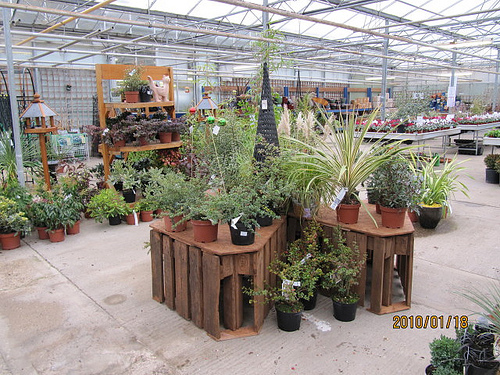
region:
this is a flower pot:
[255, 280, 318, 335]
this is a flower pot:
[326, 276, 358, 321]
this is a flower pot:
[221, 200, 262, 245]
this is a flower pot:
[185, 203, 222, 238]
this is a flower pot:
[140, 173, 191, 225]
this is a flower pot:
[295, 130, 391, 220]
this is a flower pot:
[368, 160, 410, 226]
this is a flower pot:
[403, 150, 468, 240]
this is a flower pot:
[418, 336, 458, 371]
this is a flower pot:
[94, 187, 131, 225]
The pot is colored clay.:
[184, 195, 234, 249]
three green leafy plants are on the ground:
[266, 214, 374, 336]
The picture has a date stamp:
[390, 307, 475, 347]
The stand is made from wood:
[156, 212, 246, 336]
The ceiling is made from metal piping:
[167, 30, 212, 74]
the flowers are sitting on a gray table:
[357, 110, 457, 153]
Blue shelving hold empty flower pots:
[337, 77, 379, 119]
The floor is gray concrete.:
[40, 260, 126, 341]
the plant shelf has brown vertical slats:
[141, 213, 224, 344]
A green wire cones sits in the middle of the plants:
[250, 56, 290, 158]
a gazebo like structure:
[13, 90, 65, 142]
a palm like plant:
[299, 100, 400, 237]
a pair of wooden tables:
[150, 185, 443, 337]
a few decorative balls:
[167, 99, 234, 135]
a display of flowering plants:
[352, 105, 469, 138]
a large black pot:
[416, 200, 451, 232]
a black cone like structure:
[246, 62, 298, 199]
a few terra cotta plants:
[21, 216, 85, 241]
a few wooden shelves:
[83, 55, 190, 209]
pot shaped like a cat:
[143, 70, 180, 112]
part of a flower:
[291, 275, 303, 294]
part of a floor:
[50, 229, 80, 330]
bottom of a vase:
[288, 324, 294, 329]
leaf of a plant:
[231, 172, 243, 179]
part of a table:
[439, 145, 466, 177]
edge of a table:
[424, 121, 444, 136]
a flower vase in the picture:
[267, 298, 306, 331]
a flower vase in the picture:
[331, 293, 361, 323]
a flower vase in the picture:
[223, 213, 256, 253]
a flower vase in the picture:
[418, 204, 447, 231]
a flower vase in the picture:
[379, 206, 411, 233]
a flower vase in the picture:
[338, 202, 363, 228]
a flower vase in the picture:
[0, 234, 22, 256]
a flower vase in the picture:
[45, 221, 70, 251]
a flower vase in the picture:
[123, 211, 138, 229]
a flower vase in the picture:
[123, 87, 145, 107]